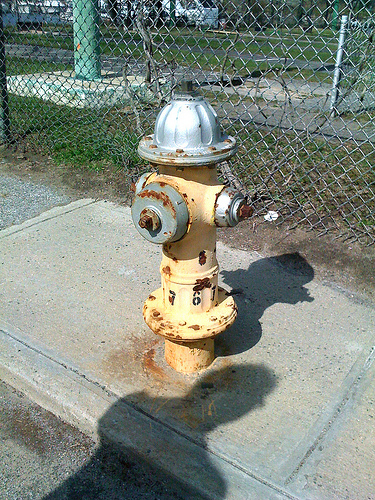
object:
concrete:
[0, 151, 374, 499]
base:
[5, 67, 167, 109]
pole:
[72, 0, 101, 80]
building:
[0, 1, 218, 27]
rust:
[162, 265, 171, 275]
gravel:
[1, 167, 373, 498]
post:
[328, 13, 347, 119]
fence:
[0, 2, 374, 251]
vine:
[134, 0, 166, 108]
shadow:
[168, 251, 316, 369]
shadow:
[40, 361, 280, 498]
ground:
[0, 25, 374, 498]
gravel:
[0, 377, 195, 499]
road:
[0, 376, 211, 499]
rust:
[198, 250, 207, 267]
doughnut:
[2, 1, 375, 249]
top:
[136, 77, 237, 167]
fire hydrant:
[129, 79, 254, 374]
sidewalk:
[0, 168, 373, 498]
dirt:
[0, 137, 374, 302]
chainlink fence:
[0, 1, 374, 249]